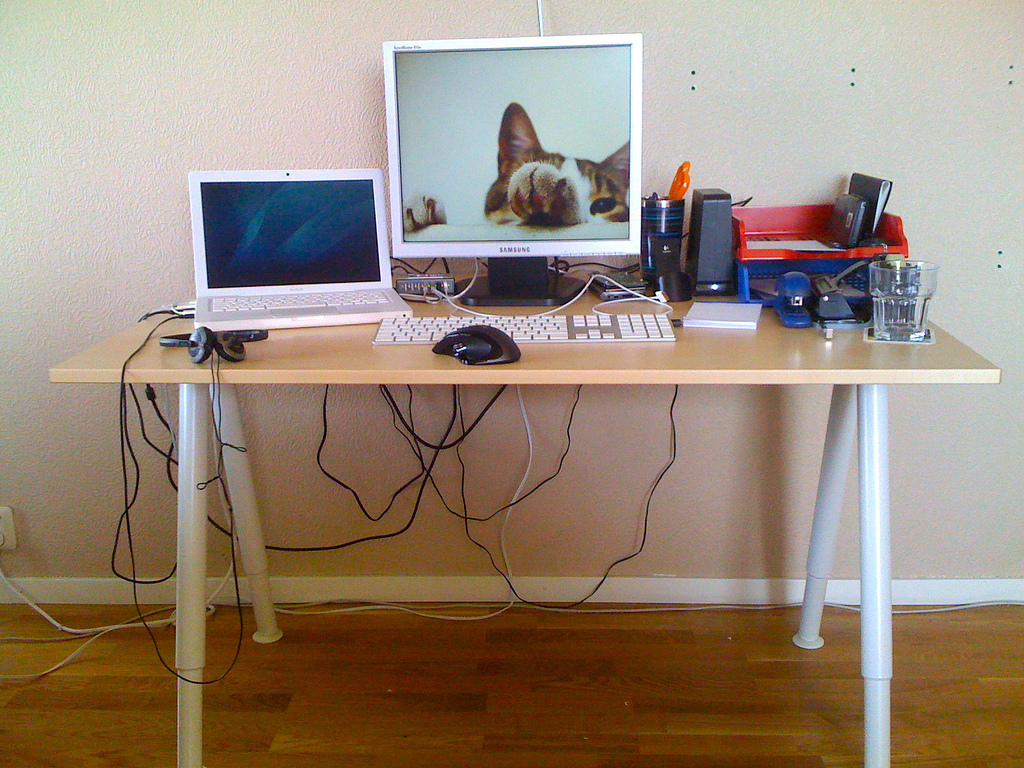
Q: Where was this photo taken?
A: In a home.